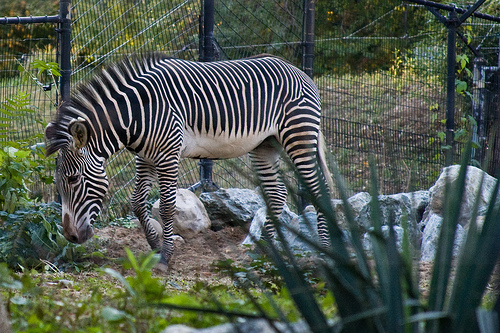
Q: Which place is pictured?
A: It is a zoo.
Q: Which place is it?
A: It is a zoo.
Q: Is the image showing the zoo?
A: Yes, it is showing the zoo.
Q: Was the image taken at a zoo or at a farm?
A: It was taken at a zoo.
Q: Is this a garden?
A: No, it is a zoo.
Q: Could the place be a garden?
A: No, it is a zoo.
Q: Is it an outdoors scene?
A: Yes, it is outdoors.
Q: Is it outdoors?
A: Yes, it is outdoors.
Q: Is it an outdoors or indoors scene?
A: It is outdoors.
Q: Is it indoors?
A: No, it is outdoors.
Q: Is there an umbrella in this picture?
A: No, there are no umbrellas.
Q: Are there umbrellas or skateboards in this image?
A: No, there are no umbrellas or skateboards.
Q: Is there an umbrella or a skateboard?
A: No, there are no umbrellas or skateboards.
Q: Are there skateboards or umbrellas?
A: No, there are no umbrellas or skateboards.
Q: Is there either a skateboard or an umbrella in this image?
A: No, there are no umbrellas or skateboards.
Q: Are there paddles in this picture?
A: No, there are no paddles.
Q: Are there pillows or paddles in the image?
A: No, there are no paddles or pillows.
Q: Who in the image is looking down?
A: The animal is looking down.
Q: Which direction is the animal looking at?
A: The animal is looking down.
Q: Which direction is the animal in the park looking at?
A: The animal is looking down.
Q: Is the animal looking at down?
A: Yes, the animal is looking down.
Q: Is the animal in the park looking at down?
A: Yes, the animal is looking down.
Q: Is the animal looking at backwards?
A: No, the animal is looking down.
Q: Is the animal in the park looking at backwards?
A: No, the animal is looking down.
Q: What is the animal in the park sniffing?
A: The animal is sniffing the plant.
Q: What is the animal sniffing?
A: The animal is sniffing the plant.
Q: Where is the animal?
A: The animal is in the park.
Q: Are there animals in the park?
A: Yes, there is an animal in the park.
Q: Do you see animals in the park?
A: Yes, there is an animal in the park.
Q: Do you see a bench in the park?
A: No, there is an animal in the park.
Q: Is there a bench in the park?
A: No, there is an animal in the park.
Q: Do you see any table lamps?
A: No, there are no table lamps.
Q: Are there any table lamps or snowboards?
A: No, there are no table lamps or snowboards.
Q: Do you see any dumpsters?
A: No, there are no dumpsters.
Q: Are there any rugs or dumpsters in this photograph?
A: No, there are no dumpsters or rugs.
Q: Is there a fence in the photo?
A: Yes, there is a fence.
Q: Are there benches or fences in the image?
A: Yes, there is a fence.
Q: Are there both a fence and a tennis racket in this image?
A: No, there is a fence but no rackets.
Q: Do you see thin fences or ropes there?
A: Yes, there is a thin fence.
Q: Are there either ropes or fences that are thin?
A: Yes, the fence is thin.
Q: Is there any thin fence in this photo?
A: Yes, there is a thin fence.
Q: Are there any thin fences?
A: Yes, there is a thin fence.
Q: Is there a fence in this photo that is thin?
A: Yes, there is a fence that is thin.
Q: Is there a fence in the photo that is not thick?
A: Yes, there is a thin fence.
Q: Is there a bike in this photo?
A: No, there are no bikes.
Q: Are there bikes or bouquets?
A: No, there are no bikes or bouquets.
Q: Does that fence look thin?
A: Yes, the fence is thin.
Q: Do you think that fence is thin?
A: Yes, the fence is thin.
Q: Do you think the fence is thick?
A: No, the fence is thin.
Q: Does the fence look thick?
A: No, the fence is thin.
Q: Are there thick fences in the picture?
A: No, there is a fence but it is thin.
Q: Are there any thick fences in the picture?
A: No, there is a fence but it is thin.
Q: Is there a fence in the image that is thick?
A: No, there is a fence but it is thin.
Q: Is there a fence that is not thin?
A: No, there is a fence but it is thin.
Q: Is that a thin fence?
A: Yes, that is a thin fence.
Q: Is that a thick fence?
A: No, that is a thin fence.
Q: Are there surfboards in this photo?
A: No, there are no surfboards.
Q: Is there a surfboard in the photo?
A: No, there are no surfboards.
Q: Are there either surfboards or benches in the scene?
A: No, there are no surfboards or benches.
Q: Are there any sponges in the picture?
A: No, there are no sponges.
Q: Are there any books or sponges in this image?
A: No, there are no sponges or books.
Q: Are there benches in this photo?
A: No, there are no benches.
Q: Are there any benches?
A: No, there are no benches.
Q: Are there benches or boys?
A: No, there are no benches or boys.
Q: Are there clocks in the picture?
A: No, there are no clocks.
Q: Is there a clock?
A: No, there are no clocks.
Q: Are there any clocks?
A: No, there are no clocks.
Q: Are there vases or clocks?
A: No, there are no clocks or vases.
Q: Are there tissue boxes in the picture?
A: No, there are no tissue boxes.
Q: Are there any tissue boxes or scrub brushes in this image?
A: No, there are no tissue boxes or scrub brushes.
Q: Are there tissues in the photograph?
A: No, there are no tissues.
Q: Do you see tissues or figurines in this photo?
A: No, there are no tissues or figurines.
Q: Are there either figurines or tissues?
A: No, there are no tissues or figurines.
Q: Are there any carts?
A: No, there are no carts.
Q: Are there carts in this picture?
A: No, there are no carts.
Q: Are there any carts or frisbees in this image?
A: No, there are no carts or frisbees.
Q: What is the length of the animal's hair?
A: The hair is short.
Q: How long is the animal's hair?
A: The hair is short.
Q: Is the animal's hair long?
A: No, the hair is short.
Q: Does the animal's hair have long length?
A: No, the hair is short.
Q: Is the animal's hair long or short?
A: The hair is short.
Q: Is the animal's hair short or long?
A: The hair is short.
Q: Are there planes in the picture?
A: No, there are no planes.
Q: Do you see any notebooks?
A: No, there are no notebooks.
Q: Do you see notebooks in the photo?
A: No, there are no notebooks.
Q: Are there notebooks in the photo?
A: No, there are no notebooks.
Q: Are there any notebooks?
A: No, there are no notebooks.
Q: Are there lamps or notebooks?
A: No, there are no notebooks or lamps.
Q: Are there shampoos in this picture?
A: No, there are no shampoos.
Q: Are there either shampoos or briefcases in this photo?
A: No, there are no shampoos or briefcases.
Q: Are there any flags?
A: No, there are no flags.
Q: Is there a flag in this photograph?
A: No, there are no flags.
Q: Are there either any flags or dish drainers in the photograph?
A: No, there are no flags or dish drainers.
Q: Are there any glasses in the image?
A: No, there are no glasses.